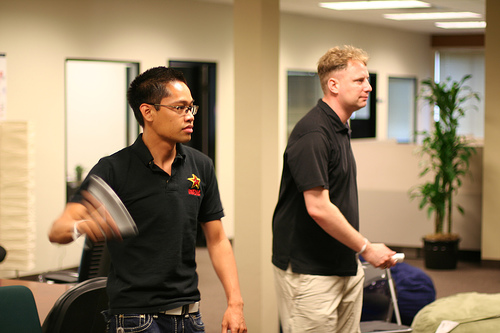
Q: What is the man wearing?
A: Shirt.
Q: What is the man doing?
A: Playing.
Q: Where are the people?
A: A room.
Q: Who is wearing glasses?
A: A man.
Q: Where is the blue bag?
A: Floor.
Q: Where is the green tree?
A: In corner.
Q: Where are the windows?
A: Behind men.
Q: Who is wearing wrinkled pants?
A: White man.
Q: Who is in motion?
A: The dark man.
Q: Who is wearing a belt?
A: The dark man.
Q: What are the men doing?
A: Playing a video game.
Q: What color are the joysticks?
A: White.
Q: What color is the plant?
A: Green.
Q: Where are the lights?
A: The ceiling.